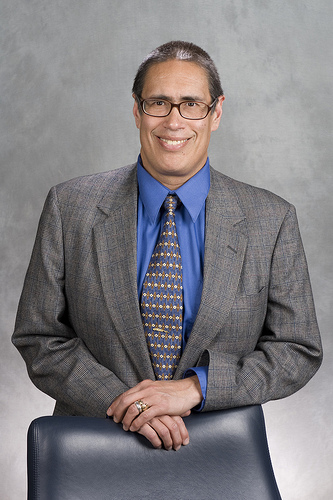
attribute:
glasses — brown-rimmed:
[146, 99, 215, 122]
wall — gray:
[0, 2, 330, 497]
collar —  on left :
[128, 166, 165, 225]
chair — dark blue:
[9, 390, 274, 499]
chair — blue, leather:
[24, 402, 282, 499]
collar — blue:
[126, 159, 233, 225]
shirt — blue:
[188, 235, 203, 271]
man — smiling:
[11, 40, 323, 451]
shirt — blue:
[131, 152, 207, 410]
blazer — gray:
[6, 142, 323, 446]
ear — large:
[202, 76, 237, 138]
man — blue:
[16, 34, 311, 487]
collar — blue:
[134, 153, 209, 227]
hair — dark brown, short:
[129, 41, 223, 115]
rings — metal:
[108, 388, 169, 432]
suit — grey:
[12, 161, 323, 418]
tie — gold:
[133, 195, 184, 379]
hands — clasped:
[103, 377, 199, 453]